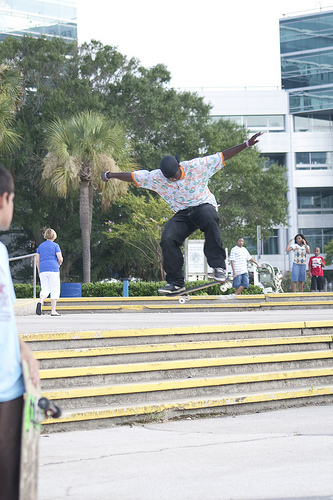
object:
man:
[98, 129, 265, 296]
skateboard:
[165, 276, 235, 305]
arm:
[195, 129, 263, 178]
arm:
[101, 169, 158, 191]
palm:
[49, 166, 77, 199]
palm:
[78, 109, 118, 137]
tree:
[0, 30, 171, 113]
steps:
[22, 320, 333, 416]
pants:
[159, 202, 227, 289]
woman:
[32, 226, 64, 319]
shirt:
[35, 239, 62, 273]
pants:
[39, 270, 62, 301]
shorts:
[232, 272, 251, 289]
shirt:
[308, 256, 327, 277]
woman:
[286, 234, 311, 294]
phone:
[302, 237, 305, 245]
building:
[256, 4, 333, 295]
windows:
[195, 113, 286, 136]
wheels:
[165, 275, 233, 304]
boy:
[229, 234, 260, 297]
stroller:
[257, 262, 285, 295]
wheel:
[37, 395, 61, 420]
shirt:
[130, 149, 227, 213]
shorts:
[291, 262, 306, 282]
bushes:
[82, 280, 123, 298]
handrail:
[7, 252, 37, 263]